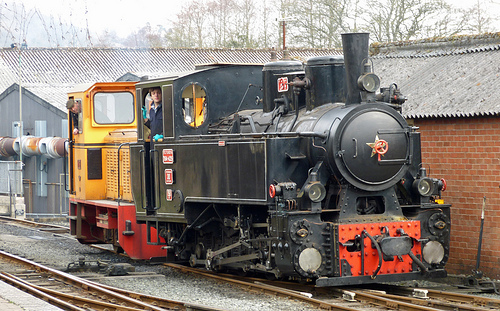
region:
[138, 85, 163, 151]
a conductor standing in the door of a train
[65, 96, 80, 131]
a man looking out of a window on the train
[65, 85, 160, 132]
two men on the train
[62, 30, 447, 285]
a black and yellow train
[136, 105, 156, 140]
blue gloves on the man's hands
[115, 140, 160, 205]
metal bars on the side of the train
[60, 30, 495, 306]
a train on the railroad tracks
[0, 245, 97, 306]
brown steel railroad tracks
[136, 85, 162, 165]
a conductor on the train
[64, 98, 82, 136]
an engineer on the train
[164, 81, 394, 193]
The train is the color black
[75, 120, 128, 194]
The train has yellow on it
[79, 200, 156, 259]
The train has red on it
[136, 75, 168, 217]
The door to the train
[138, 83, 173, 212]
The man in the door way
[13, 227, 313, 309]
The gravel on the ground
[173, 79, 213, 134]
The window of the train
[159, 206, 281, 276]
The mechanics of the train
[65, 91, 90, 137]
The man is sticking his head out of window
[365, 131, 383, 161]
THE STAR IS ON THE FRONT OF THE TRAIN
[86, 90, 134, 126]
THE WINDOW IS ON THE TRAIN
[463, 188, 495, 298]
THE SWITCH IS NEXT TO THE TRACK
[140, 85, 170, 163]
THE ENGINEER IS ON THE TRAIN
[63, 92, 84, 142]
THE CONDUCTOR IS ON THE TRAIN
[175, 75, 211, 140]
THE WINDOW IS ROUND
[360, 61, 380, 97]
THE LIGHT IS ROUND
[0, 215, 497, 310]
THE GRAVEL IS AROUND THE TRACKS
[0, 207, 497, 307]
THE TRACKS ARE SIDE BY SIDE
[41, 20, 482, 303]
THE TRAIN IS ON THE TRACKS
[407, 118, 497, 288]
Brick is on the wall.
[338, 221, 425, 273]
The metal plate is red.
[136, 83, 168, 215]
A man is in a door.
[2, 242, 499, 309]
Rail tracks are brown.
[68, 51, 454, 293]
The engine is old.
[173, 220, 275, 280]
The arms are down.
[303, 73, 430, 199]
Three lights are off.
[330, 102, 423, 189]
A star is on the circle.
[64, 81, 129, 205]
A cab is yellow.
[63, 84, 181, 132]
Two men are looking out of openings.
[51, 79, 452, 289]
train car on track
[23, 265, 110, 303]
train track with no train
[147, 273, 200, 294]
gravel between tracks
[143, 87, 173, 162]
person on train car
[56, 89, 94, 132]
person on train car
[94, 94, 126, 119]
window on the train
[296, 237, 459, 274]
light on the train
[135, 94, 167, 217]
door on the train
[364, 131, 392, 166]
image on the train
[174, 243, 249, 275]
wheels on the train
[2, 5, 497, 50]
The cloudy sky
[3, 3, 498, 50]
A cloudy sky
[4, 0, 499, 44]
A set of barren trees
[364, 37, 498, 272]
The red brick building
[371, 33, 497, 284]
A red brick building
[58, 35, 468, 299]
The black train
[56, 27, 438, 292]
A black train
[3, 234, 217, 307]
The train tracks to the left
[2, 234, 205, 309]
A set of train tracks to the left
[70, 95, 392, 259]
big black train on rail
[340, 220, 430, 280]
red metal frame on front side